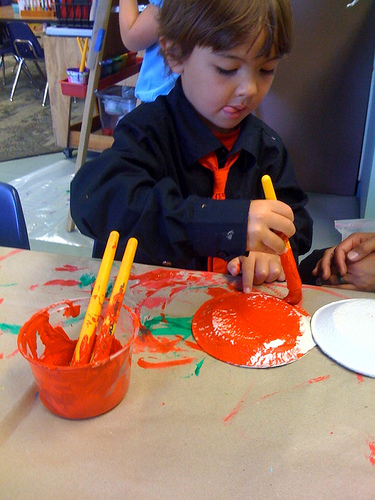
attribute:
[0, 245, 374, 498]
table — brown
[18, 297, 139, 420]
paint — red, orange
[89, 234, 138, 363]
brush — yellow, thick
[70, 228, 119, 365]
brush — yellow, thick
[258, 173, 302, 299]
brush — yellow, thick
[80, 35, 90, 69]
brush — yellow, thick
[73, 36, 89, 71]
brush — yellow, thick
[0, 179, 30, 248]
chair — blue, plastic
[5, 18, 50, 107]
chair — blue, plastic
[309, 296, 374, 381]
plate — white, paper, plain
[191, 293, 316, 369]
plate — white, paper, painted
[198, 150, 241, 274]
tie — red, orange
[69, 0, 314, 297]
child — painting, careful, little, young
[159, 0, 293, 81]
hair — brown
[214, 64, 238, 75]
eyelashes — long, thick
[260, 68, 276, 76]
eyelashes — long, thick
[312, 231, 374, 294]
hands — clasped, adult